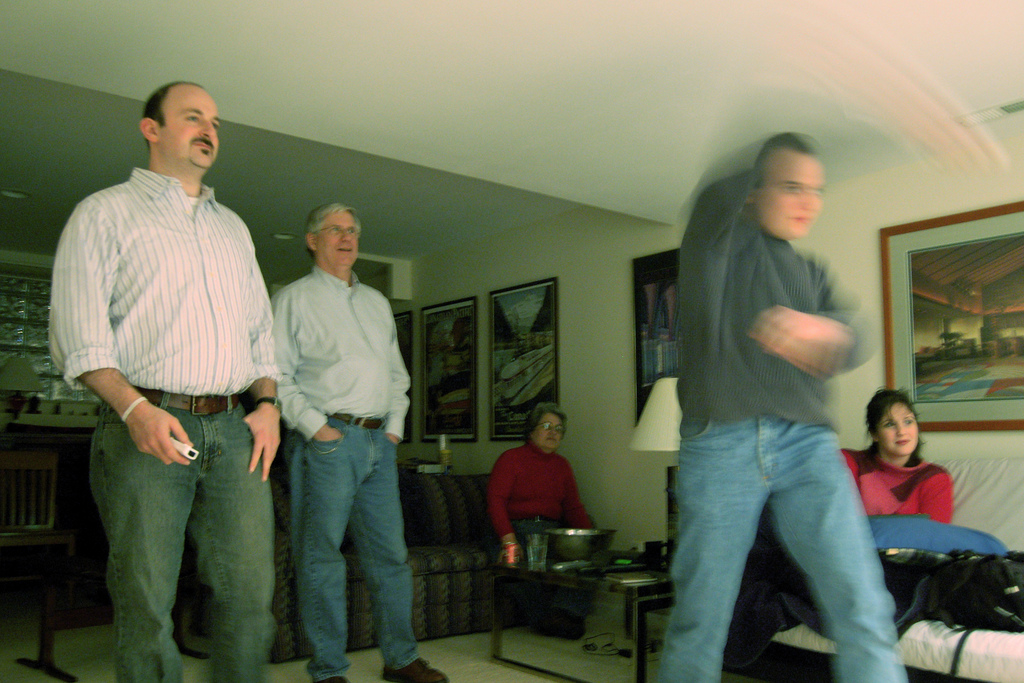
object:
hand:
[311, 424, 342, 443]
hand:
[381, 431, 401, 446]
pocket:
[308, 423, 344, 442]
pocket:
[373, 429, 399, 460]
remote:
[168, 435, 199, 460]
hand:
[123, 400, 196, 467]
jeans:
[290, 413, 429, 683]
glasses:
[537, 421, 565, 433]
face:
[532, 411, 565, 449]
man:
[274, 201, 460, 683]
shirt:
[46, 165, 281, 395]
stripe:
[101, 189, 153, 388]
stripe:
[171, 178, 217, 396]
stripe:
[93, 348, 103, 370]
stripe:
[68, 213, 81, 353]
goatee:
[189, 135, 219, 170]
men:
[48, 78, 907, 683]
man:
[48, 77, 283, 683]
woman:
[485, 394, 596, 572]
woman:
[842, 387, 954, 526]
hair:
[865, 385, 921, 438]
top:
[840, 447, 953, 503]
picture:
[874, 199, 1023, 435]